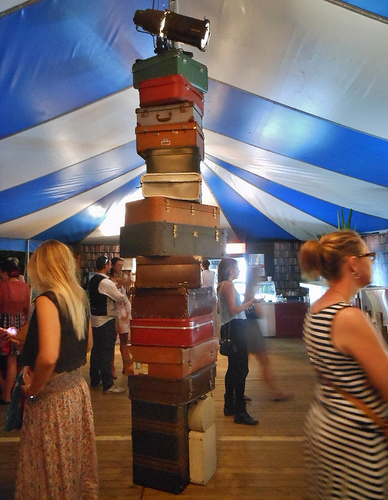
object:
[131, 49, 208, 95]
box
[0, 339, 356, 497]
floor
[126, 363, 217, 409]
suitcase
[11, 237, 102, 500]
woman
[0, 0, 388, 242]
tent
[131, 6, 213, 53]
light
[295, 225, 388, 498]
person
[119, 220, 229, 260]
luggage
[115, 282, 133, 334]
dress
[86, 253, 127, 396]
man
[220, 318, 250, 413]
pant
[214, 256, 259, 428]
people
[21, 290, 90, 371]
coat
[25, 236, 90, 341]
hair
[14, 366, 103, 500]
blouse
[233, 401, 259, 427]
shoe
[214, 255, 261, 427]
lady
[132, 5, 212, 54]
spectacle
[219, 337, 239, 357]
bag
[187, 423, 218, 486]
box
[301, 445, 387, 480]
stripe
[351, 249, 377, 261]
glass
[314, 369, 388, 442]
strap